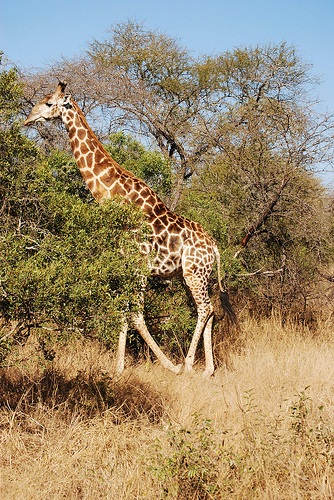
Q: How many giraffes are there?
A: One.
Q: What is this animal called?
A: Giraffe.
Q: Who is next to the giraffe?
A: No one.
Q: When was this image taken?
A: Daytime.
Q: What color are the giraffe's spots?
A: Brown.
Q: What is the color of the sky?
A: Blue.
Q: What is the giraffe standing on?
A: The ground.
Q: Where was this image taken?
A: In a field.